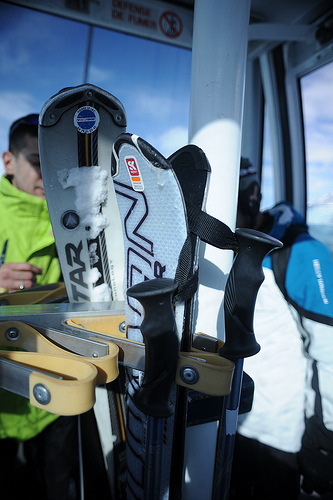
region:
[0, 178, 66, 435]
a neon yellow winter jacket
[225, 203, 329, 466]
a blue and white winter coat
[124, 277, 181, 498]
a black handled ski pole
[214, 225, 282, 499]
a black handled ski pole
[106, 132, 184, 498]
a reflective grey ski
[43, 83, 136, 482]
a reflective grey ski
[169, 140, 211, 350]
black bottom of a ski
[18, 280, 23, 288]
a man's silver ring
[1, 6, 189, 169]
a cloudy blue sky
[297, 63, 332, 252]
a cloudy blue sky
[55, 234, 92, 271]
this is the letter R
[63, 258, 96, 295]
this is the letter A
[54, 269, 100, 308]
this is the letter T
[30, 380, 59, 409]
this is a bolt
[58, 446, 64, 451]
this is the color black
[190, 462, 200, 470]
this is the color gray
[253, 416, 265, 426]
this is the color white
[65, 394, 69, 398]
this is the color brown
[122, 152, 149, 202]
this is a sticker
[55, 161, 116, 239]
this is white snow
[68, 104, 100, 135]
small tag on end of ski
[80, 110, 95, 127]
blue inside of small tag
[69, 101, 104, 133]
white boarder of tag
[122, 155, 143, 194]
tag on end of skis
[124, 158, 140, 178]
red box on front of skis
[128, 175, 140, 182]
orange box on tag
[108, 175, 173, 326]
black writing on front of ski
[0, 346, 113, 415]
tan straps on bottom of ski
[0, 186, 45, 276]
green snow jacket on man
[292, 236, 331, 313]
blue snow jacket on man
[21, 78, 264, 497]
a set of skis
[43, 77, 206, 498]
set of skis are grey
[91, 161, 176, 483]
black writing on ski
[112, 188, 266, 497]
a set of ski poles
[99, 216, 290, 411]
black handles on ski poles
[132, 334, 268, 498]
ski poles are silver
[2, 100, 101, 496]
this is a man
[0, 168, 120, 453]
man wearing a green jacket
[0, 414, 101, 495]
man wearing black pants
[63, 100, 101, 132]
blue sticker on skis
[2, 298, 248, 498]
this is a ski rack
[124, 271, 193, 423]
the black handle of a ski pole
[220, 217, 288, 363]
the rubber handle of the ski pole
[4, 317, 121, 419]
these slots are for skis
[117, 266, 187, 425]
the ski pole grip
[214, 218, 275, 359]
a black ski poke grip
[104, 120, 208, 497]
this is a pair of skis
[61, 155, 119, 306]
there is snow on the skis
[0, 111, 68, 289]
he is wearing a neon green jacket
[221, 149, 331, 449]
his jacket is white and blue